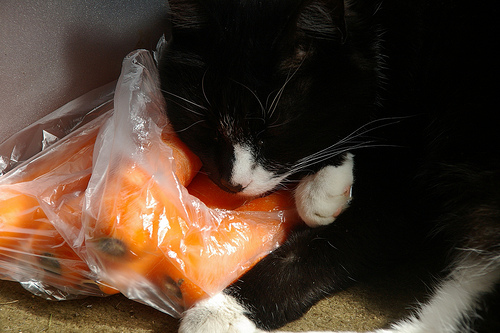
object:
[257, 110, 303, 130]
eye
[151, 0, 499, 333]
cat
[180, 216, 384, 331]
leg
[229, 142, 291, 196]
white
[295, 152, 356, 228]
white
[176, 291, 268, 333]
white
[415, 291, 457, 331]
white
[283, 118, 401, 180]
whiskers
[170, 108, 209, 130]
eyes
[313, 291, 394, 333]
floor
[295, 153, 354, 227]
paw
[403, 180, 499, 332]
legs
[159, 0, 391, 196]
head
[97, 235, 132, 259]
stem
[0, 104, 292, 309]
carrot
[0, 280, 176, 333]
floor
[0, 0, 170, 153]
wall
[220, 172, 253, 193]
nose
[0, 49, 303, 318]
bag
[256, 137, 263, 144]
tears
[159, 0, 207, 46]
cat ear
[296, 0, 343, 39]
cat ear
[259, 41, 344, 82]
hair